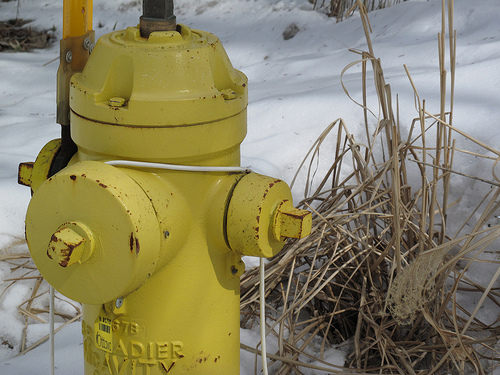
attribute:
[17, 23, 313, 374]
fire hydrant — yellow, rusty, worn, painted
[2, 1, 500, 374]
snow — white, over hill, covering ground, on ground, shadowy, sloped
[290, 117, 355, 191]
stalk — dead, bent, curled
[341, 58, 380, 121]
stalk — dead, bent, curled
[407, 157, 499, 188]
stalk — dead, bent, curled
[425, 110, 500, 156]
stalk — dead, bent, curled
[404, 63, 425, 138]
stalk — bent, dead, curled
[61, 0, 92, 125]
pole — yellow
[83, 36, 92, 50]
screw — metal, silver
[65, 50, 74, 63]
screw — metal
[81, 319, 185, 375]
lettering — raised, yellow, manufacturer name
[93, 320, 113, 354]
sticker — yellow, black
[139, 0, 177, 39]
plug — metal, silver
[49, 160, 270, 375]
cord — wired, white, horizontal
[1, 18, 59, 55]
debris — brown, dead, dry, grass, tan, straw, piled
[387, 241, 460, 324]
plant — dead, tan, whispy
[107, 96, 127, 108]
bolt — metal, yellow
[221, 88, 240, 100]
bolt — yellow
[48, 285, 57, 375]
grass — dry, dead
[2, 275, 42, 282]
grass — dry, dead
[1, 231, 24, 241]
grass — dry, dead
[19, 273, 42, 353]
grass — dry, dead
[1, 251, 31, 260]
grass — dry, dead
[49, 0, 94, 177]
wrench — yellow